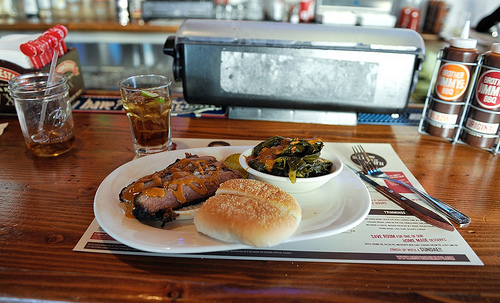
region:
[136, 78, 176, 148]
the glass has ice tea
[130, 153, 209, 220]
there is sauce on the meat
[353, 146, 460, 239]
there is fork and knife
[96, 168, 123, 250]
the plate is white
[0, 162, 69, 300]
the table is wooden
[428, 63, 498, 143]
there are two bottles of bbq sauce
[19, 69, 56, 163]
spoon is in the jar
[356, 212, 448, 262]
this is a paper table mat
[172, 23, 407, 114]
a warmer is on the grill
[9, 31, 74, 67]
there are red spoons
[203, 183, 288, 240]
this is a snack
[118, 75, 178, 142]
this is a glass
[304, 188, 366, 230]
this is a plate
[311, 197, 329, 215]
the plate is white in color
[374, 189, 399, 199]
this is a knife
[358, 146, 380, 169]
this is a fox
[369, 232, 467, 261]
this is a table mat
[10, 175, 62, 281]
this is a table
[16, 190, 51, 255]
the table is wooden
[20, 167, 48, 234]
the table is brown in color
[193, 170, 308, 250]
bun top with seeds on it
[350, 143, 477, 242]
fork and knife with wood handle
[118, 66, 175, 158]
drinking glass part filled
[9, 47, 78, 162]
mug type glass with a straw in it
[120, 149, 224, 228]
hot dog with many toppings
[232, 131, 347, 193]
green vegetable with topping on it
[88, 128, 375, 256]
white oblong plate with three types of food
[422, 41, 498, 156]
two condiment bottles with orange and red label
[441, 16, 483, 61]
white pointed bottle top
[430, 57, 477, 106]
round orange label with MMM BBQ words on it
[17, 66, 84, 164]
A straw sits in an almost empty glass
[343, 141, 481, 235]
Utensils rest next to a plate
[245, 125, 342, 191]
Greens fill a small bowl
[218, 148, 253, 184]
A pickle hides beside a bowl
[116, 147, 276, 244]
A sandwich on a plate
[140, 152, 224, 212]
Sauce drizzled on the meat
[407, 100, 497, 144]
A selection of barbeque sauce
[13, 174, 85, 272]
A wooden table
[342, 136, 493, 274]
A paper placemat protects the table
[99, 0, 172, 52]
Shelves in the background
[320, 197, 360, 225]
this is a plate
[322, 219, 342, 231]
the plate is white in color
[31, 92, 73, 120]
the glass is shinny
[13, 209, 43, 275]
this is s a table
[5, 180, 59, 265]
the table is wooden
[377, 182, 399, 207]
this is a knife